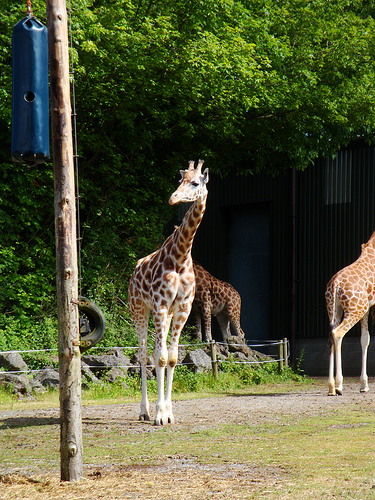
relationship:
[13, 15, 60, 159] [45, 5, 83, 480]
bag hanging down from pole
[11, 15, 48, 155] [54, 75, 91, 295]
bag hanging down from pole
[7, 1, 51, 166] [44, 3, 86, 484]
bag hanging down from pole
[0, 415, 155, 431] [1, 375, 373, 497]
shadow on ground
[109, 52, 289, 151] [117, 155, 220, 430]
trees behind giraffe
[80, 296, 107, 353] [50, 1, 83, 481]
tube on post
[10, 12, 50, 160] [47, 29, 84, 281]
bag hanging from pole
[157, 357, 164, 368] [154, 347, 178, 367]
brown spot on knees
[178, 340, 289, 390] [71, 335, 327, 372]
rocks on other side of fence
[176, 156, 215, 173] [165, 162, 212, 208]
knubs on head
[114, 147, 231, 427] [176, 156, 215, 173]
giraffe has knubs